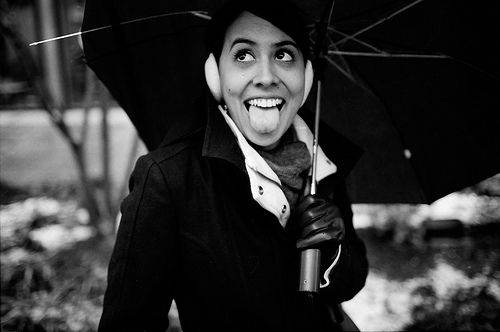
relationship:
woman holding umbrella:
[97, 3, 372, 332] [80, 2, 498, 296]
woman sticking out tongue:
[97, 3, 372, 332] [247, 102, 283, 139]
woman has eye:
[97, 3, 372, 332] [229, 46, 261, 68]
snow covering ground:
[1, 185, 95, 280] [2, 167, 499, 327]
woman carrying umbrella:
[97, 3, 372, 332] [80, 2, 498, 296]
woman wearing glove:
[97, 3, 372, 332] [288, 192, 347, 256]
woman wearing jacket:
[97, 3, 372, 332] [98, 107, 372, 332]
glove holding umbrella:
[288, 192, 347, 256] [80, 2, 498, 296]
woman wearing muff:
[97, 3, 372, 332] [199, 49, 224, 107]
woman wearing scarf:
[97, 3, 372, 332] [238, 121, 318, 244]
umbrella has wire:
[80, 2, 498, 296] [22, 0, 182, 52]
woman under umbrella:
[97, 3, 372, 332] [80, 2, 498, 296]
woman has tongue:
[97, 3, 372, 332] [247, 102, 283, 139]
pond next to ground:
[3, 98, 499, 229] [2, 167, 499, 327]